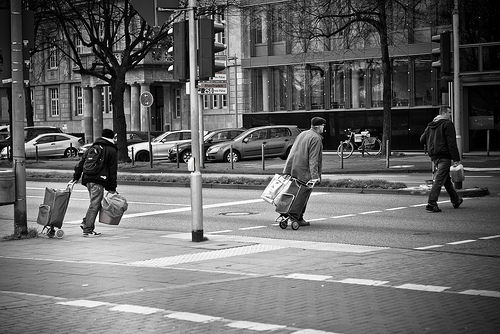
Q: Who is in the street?
A: The men.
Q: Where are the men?
A: In the street.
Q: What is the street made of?
A: Asphalt.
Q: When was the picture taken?
A: Daytime.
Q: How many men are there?
A: Three.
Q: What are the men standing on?
A: The street.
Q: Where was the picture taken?
A: In a city.